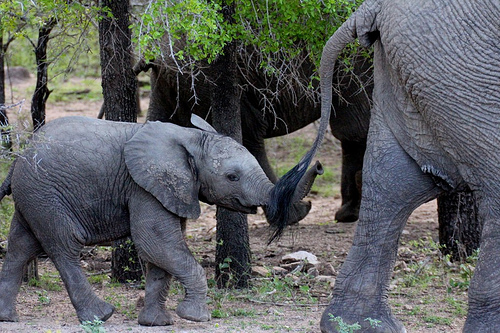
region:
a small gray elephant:
[23, 104, 350, 313]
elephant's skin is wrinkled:
[350, 13, 442, 230]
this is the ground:
[276, 313, 297, 324]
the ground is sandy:
[219, 319, 246, 331]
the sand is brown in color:
[254, 318, 299, 331]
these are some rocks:
[257, 245, 330, 284]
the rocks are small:
[276, 245, 316, 278]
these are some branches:
[124, 11, 321, 47]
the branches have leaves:
[155, 3, 297, 59]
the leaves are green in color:
[154, 3, 292, 48]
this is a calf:
[17, 87, 272, 316]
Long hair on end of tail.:
[271, 161, 322, 233]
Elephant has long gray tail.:
[308, 30, 380, 181]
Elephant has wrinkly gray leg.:
[340, 145, 400, 330]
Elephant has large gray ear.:
[120, 125, 218, 209]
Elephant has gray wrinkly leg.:
[133, 209, 233, 329]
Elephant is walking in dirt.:
[26, 219, 235, 331]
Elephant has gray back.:
[36, 119, 100, 168]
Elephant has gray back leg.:
[38, 238, 132, 320]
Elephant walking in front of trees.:
[63, 101, 320, 301]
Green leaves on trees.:
[193, 0, 213, 47]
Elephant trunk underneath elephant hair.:
[302, 156, 336, 217]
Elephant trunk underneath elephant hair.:
[179, 108, 223, 138]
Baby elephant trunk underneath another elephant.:
[200, 118, 285, 219]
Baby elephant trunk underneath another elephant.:
[195, 16, 237, 33]